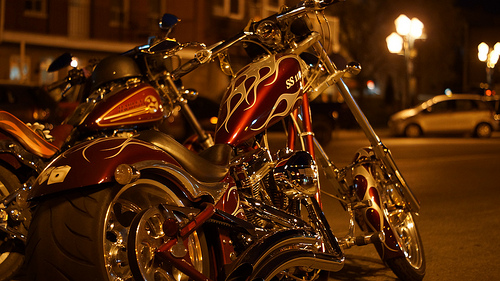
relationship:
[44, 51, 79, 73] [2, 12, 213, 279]
mirror on motorcycle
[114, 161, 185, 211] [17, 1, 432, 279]
taillight of motorcyle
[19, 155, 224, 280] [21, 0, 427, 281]
wheel on motorcycle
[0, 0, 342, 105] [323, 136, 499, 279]
building near street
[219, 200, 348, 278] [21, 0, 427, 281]
muffler on motorcycle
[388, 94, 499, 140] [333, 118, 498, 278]
car on street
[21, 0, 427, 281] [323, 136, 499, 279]
motorcycle on street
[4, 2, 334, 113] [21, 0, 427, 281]
building behind motorcycle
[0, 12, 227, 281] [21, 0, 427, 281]
motorcycle behind motorcycle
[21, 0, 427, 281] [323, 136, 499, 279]
motorcycle parked on street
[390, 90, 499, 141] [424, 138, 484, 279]
car parked on street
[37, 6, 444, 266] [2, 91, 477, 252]
motorcycle parked on street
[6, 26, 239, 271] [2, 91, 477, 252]
motorcycle parked on street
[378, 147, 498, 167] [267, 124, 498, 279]
line painted on pavement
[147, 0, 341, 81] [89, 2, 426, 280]
handlebar attached to motorcycle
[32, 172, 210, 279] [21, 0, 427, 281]
fat/back tire attached to motorcycle